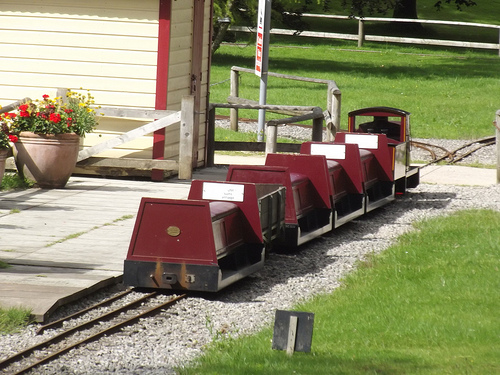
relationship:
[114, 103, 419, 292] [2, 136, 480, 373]
cart sitting on track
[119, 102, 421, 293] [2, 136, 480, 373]
train sitting on track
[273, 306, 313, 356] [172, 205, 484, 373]
sign stuck in grass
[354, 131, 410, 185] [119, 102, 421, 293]
engine powering train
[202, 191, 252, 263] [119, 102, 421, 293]
bench built into train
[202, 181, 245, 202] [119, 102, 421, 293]
sign stuck on train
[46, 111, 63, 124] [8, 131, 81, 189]
flower planted in pot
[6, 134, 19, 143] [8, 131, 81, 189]
flower planted in pot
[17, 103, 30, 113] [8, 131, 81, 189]
flower planted in pot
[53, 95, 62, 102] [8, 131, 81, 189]
flower planted in pot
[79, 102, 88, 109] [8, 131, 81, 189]
flower planted in pot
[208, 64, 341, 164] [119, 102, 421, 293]
fence standing next to train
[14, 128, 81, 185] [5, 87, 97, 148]
pot with flowers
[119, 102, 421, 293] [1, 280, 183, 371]
train on tracks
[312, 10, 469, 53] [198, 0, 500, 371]
fence on grass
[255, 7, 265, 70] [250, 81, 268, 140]
sign on post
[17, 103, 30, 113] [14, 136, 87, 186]
flower in pot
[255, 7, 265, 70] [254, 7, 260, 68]
sign with writing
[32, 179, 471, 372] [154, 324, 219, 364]
path on ground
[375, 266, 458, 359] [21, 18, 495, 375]
grass in garden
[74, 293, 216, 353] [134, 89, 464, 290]
ballast facilitating water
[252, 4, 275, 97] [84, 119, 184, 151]
sign on stick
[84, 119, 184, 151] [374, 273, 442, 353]
stick coming grass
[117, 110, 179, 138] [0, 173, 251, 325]
wood used deck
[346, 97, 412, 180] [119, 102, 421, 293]
cart on train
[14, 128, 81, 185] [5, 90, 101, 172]
pot of flowers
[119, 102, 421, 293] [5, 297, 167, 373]
train of track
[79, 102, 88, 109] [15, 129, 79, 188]
flower in pot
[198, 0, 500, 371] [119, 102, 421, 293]
grass around train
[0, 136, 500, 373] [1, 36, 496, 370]
tracks on ground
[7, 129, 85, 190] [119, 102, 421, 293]
planter near train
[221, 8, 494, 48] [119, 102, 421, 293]
fence near train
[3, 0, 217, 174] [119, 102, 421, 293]
building near train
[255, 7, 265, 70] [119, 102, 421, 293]
sign near train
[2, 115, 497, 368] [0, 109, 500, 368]
rocks around tracks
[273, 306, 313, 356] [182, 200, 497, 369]
sign in grass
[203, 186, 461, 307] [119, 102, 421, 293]
shadow from train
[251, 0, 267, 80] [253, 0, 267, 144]
sign on pole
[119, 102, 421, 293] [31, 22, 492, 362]
train in garden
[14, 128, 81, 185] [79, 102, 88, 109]
pot has flower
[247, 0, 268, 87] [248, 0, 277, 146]
sign on pole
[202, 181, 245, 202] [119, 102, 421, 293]
sign on train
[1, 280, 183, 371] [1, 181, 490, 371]
tracks are on gravel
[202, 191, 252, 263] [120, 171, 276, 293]
bench in cart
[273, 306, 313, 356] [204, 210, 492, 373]
sign in grass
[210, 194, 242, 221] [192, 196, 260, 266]
cushion in seat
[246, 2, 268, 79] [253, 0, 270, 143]
sign in pole